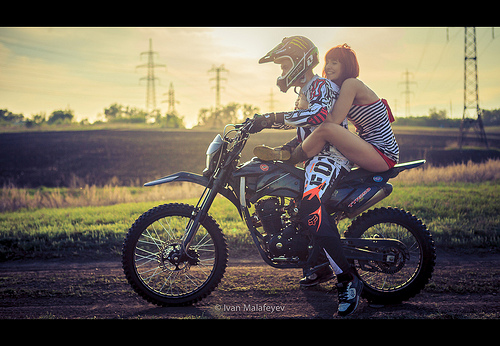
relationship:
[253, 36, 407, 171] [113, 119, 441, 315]
couple riding on motorbike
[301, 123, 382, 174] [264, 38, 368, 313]
leg around guy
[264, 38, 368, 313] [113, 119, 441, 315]
man riding on bike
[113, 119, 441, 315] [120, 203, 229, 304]
bike has front tire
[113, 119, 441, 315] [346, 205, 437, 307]
bike has back tire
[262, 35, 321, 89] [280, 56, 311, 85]
helmet on top of head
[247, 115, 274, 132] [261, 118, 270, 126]
hand holding onto handlebar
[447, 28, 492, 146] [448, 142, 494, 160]
pole above ground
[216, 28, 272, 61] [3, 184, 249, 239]
sun shining on land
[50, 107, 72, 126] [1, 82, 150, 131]
tree visible in distance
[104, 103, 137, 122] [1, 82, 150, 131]
tree visible in distance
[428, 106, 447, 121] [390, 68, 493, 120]
tree visible in distance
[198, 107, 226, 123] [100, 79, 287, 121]
tree visible in distance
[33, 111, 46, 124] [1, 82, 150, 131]
tree visible in distance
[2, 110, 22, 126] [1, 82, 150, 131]
tree visible in distance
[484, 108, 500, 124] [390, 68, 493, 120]
tree visible in distance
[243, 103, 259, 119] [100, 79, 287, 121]
tree visible in distance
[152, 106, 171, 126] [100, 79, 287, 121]
tree visible in distance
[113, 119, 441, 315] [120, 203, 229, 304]
motorcycle has front tire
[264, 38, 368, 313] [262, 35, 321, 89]
man wearing helmet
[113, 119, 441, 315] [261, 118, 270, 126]
motorcycle has handlebar